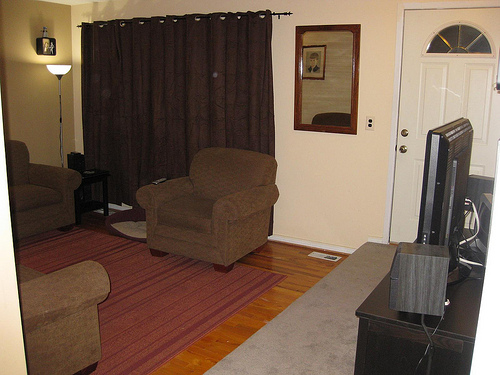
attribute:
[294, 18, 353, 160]
mirror — framed, wood, hanging, brown, wooden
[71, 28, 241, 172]
curtains — close, brown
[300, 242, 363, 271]
vent — white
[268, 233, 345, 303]
floor — wood, brown, wooden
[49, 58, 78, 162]
lamp — lit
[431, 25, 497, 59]
window — arched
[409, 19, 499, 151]
door — cream, white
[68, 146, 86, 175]
speaker — black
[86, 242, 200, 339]
rug — red, mauve, striped, maroon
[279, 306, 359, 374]
carpet — gray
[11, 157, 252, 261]
chairs — brown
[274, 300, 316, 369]
rug — gray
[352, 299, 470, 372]
furniture — black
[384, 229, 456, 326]
speaker — small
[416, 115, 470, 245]
television — black, flat, large, silver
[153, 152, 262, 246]
chair — plush, brown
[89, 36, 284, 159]
drapes — brown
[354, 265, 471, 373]
entertainment center — black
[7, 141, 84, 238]
seat — brown, large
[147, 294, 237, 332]
carpet — striped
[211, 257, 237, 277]
legs — wooden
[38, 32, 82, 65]
box — small